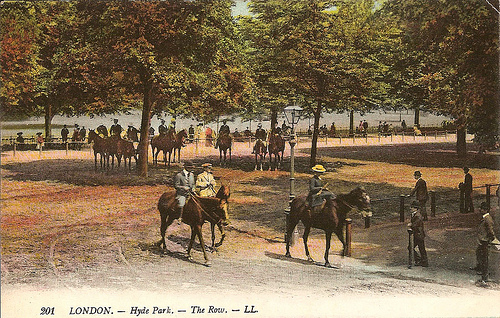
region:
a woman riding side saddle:
[306, 161, 335, 203]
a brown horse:
[280, 181, 388, 263]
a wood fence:
[331, 177, 493, 226]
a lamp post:
[282, 90, 306, 220]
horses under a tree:
[88, 115, 198, 170]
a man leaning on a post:
[405, 194, 433, 268]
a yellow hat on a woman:
[308, 161, 327, 173]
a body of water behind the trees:
[0, 93, 464, 132]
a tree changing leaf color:
[79, 5, 224, 177]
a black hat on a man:
[479, 200, 492, 209]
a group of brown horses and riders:
[69, 106, 300, 172]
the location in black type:
[66, 292, 272, 316]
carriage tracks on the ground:
[45, 228, 124, 281]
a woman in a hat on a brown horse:
[294, 160, 372, 259]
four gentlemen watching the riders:
[405, 157, 491, 292]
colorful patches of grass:
[16, 169, 109, 234]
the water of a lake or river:
[75, 93, 242, 127]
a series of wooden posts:
[335, 129, 434, 143]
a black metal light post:
[285, 99, 306, 196]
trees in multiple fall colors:
[61, 30, 496, 102]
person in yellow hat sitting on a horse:
[282, 162, 376, 268]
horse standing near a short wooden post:
[342, 218, 354, 256]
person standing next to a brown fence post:
[397, 192, 409, 217]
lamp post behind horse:
[281, 95, 300, 217]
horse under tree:
[86, 129, 127, 169]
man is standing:
[403, 200, 429, 269]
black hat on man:
[478, 201, 488, 212]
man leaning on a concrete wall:
[483, 234, 498, 280]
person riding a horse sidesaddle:
[308, 164, 336, 206]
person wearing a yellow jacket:
[196, 165, 216, 197]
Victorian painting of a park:
[82, 111, 499, 286]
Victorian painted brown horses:
[142, 147, 449, 282]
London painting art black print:
[66, 292, 279, 316]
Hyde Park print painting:
[127, 294, 186, 314]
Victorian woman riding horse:
[280, 154, 390, 281]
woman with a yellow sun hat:
[304, 157, 362, 222]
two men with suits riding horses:
[155, 157, 251, 262]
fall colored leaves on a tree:
[94, 55, 234, 176]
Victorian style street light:
[274, 97, 320, 242]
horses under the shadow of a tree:
[59, 77, 243, 189]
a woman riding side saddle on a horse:
[270, 155, 372, 242]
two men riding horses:
[156, 142, 231, 234]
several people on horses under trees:
[91, 102, 321, 170]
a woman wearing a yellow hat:
[291, 163, 346, 198]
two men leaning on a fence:
[398, 165, 490, 210]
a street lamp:
[263, 71, 328, 204]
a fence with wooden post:
[341, 127, 452, 152]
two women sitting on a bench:
[11, 130, 46, 151]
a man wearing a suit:
[173, 160, 195, 222]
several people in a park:
[31, 96, 458, 274]